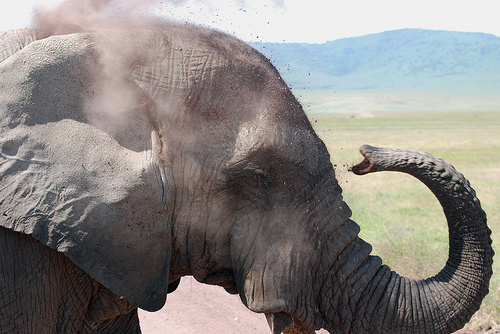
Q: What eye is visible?
A: Right eye.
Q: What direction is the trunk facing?
A: Upwards.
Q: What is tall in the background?
A: Mountains.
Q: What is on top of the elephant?
A: Dust.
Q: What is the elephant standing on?
A: Dirt ground.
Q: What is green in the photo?
A: Grass.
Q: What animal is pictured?
A: Elephant.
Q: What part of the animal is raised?
A: Trunk.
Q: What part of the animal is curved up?
A: Trunk.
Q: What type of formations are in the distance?
A: Mountains.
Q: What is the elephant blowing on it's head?
A: Dirt.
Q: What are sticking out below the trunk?
A: Tusks.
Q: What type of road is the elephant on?
A: Dirt.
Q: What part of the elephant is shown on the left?
A: Ear.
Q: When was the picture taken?
A: Daytime.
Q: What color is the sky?
A: White.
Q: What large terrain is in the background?
A: Mountains.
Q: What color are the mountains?
A: Green.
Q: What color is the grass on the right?
A: Green.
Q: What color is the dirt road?
A: Brown.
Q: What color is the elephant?
A: Gray.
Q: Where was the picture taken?
A: In a zoo.